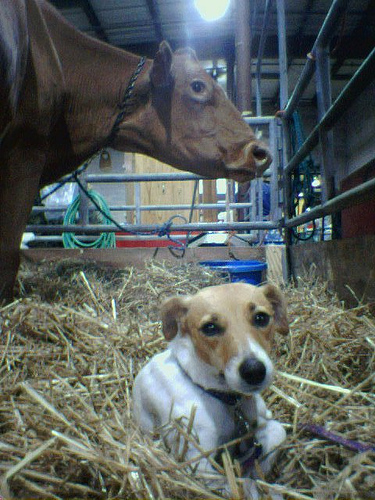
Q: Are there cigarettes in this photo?
A: No, there are no cigarettes.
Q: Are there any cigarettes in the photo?
A: No, there are no cigarettes.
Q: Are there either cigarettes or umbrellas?
A: No, there are no cigarettes or umbrellas.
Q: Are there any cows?
A: Yes, there is a cow.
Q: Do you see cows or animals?
A: Yes, there is a cow.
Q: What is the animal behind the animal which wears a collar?
A: The animal is a cow.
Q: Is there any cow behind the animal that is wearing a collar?
A: Yes, there is a cow behind the animal.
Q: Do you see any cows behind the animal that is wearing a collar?
A: Yes, there is a cow behind the animal.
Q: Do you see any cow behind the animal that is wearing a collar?
A: Yes, there is a cow behind the animal.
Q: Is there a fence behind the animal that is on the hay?
A: No, there is a cow behind the animal.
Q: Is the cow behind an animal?
A: Yes, the cow is behind an animal.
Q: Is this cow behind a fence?
A: No, the cow is behind an animal.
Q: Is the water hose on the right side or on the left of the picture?
A: The water hose is on the left of the image.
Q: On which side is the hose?
A: The hose is on the left of the image.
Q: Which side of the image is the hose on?
A: The hose is on the left of the image.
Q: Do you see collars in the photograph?
A: Yes, there is a collar.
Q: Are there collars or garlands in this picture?
A: Yes, there is a collar.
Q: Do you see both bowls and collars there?
A: No, there is a collar but no bowls.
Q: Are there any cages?
A: No, there are no cages.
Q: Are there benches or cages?
A: No, there are no cages or benches.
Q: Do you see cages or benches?
A: No, there are no cages or benches.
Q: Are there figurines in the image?
A: No, there are no figurines.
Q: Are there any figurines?
A: No, there are no figurines.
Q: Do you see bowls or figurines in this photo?
A: No, there are no figurines or bowls.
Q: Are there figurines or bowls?
A: No, there are no figurines or bowls.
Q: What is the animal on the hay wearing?
A: The animal is wearing a collar.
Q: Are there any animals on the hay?
A: Yes, there is an animal on the hay.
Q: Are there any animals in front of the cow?
A: Yes, there is an animal in front of the cow.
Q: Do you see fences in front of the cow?
A: No, there is an animal in front of the cow.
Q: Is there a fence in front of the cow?
A: No, there is an animal in front of the cow.